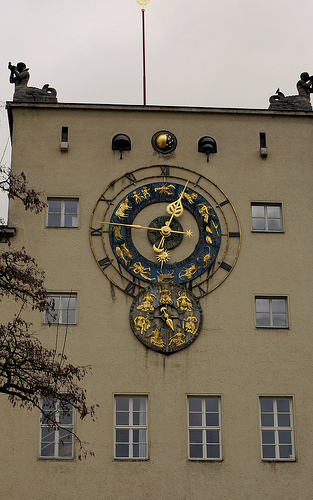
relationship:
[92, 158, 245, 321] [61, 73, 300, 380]
clock on building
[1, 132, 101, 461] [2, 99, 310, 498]
tree beside building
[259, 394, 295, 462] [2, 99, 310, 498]
window on building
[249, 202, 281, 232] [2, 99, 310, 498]
window on building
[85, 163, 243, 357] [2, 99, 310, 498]
clock on side of building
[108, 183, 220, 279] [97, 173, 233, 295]
zodiac sign on clock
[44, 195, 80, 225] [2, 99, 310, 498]
window on building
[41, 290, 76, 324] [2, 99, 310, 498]
window on building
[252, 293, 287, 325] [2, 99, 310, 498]
window on building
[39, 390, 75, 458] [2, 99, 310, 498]
window on building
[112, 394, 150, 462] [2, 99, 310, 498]
window on building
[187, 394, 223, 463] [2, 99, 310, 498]
window on building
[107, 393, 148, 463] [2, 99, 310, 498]
window on building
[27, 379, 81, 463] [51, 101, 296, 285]
window on building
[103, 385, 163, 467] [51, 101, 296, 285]
window on building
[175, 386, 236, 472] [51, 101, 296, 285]
window on building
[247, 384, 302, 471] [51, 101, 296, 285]
window on building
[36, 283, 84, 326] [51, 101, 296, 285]
window on building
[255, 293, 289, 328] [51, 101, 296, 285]
window on building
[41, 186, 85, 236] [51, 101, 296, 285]
window on building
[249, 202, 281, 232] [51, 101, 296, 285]
window on building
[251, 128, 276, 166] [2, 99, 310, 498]
buttress on building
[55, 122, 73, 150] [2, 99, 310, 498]
buttress on building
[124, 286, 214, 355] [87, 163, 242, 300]
mythological figures under clock